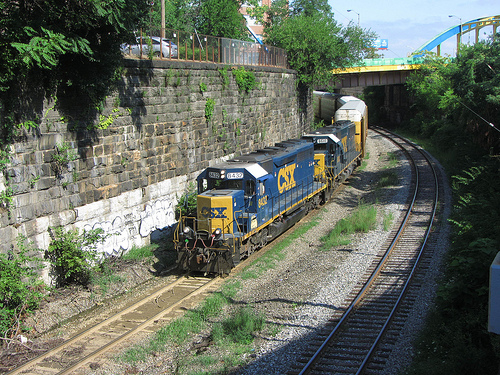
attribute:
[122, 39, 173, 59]
car — parked, white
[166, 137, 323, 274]
engine — yellow, blue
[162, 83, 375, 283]
train — colorful, long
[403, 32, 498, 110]
leafy trees — green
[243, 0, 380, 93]
leafy trees — green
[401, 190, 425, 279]
railroad track — brown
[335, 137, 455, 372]
tracks — train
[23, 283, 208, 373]
tracks — train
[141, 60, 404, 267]
engine — blue, yellow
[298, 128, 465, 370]
track — railroad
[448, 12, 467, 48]
light pole — for light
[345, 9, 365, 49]
light pole — for light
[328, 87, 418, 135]
tunnel — little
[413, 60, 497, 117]
trees — green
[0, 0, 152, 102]
tree — overhanging, large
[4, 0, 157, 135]
green tree — leafy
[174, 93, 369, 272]
train — long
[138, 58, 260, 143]
wall — brick, tall, long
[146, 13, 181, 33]
pole — wooden, tall, thin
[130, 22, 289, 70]
fence — barrier 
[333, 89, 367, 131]
roof — white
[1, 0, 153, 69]
tree — green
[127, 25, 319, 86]
fence — metal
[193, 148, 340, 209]
train — blue, yellow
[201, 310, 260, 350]
grass — green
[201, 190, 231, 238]
nose — yellow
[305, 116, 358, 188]
engine — second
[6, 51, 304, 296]
wall — brick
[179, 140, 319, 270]
engine — blue